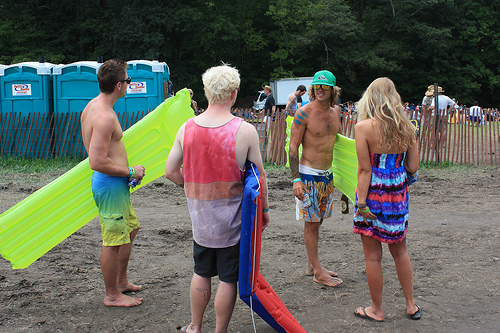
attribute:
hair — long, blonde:
[351, 71, 419, 144]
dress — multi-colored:
[351, 143, 412, 236]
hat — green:
[305, 64, 345, 93]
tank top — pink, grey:
[180, 114, 248, 244]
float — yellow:
[1, 81, 205, 269]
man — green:
[292, 63, 345, 293]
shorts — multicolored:
[82, 155, 144, 250]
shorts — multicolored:
[292, 160, 334, 230]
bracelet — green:
[355, 199, 370, 216]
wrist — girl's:
[356, 205, 373, 218]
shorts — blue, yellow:
[85, 173, 147, 255]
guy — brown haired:
[76, 56, 163, 311]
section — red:
[189, 125, 239, 185]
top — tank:
[178, 116, 252, 260]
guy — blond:
[168, 60, 273, 330]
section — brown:
[175, 174, 245, 208]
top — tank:
[181, 112, 255, 256]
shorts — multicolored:
[291, 164, 346, 235]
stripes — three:
[287, 105, 305, 136]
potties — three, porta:
[4, 51, 179, 181]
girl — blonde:
[340, 67, 448, 331]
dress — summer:
[350, 143, 420, 243]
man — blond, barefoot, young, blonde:
[163, 60, 273, 329]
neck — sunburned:
[193, 103, 237, 121]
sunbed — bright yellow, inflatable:
[4, 88, 198, 295]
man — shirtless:
[284, 66, 362, 296]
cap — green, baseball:
[304, 65, 338, 95]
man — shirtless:
[285, 67, 354, 295]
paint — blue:
[289, 105, 314, 137]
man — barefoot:
[79, 57, 149, 312]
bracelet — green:
[354, 206, 370, 217]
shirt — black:
[261, 96, 275, 118]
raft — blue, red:
[233, 163, 308, 331]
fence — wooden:
[6, 105, 491, 172]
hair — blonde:
[202, 60, 240, 106]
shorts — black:
[192, 240, 239, 285]